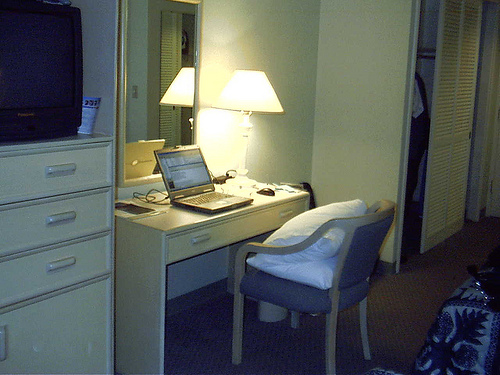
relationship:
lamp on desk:
[209, 64, 287, 183] [111, 171, 314, 374]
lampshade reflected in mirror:
[212, 64, 283, 118] [127, 0, 195, 179]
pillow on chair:
[256, 198, 366, 264] [228, 197, 396, 374]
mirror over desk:
[127, 0, 195, 179] [111, 171, 314, 374]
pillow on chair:
[252, 253, 342, 291] [228, 197, 396, 374]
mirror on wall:
[127, 0, 195, 179] [126, 2, 322, 186]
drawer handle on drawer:
[40, 161, 78, 176] [3, 142, 109, 204]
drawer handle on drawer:
[48, 211, 78, 225] [4, 185, 110, 257]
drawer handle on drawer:
[48, 255, 80, 271] [0, 227, 111, 307]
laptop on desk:
[152, 143, 256, 222] [111, 171, 314, 374]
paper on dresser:
[80, 94, 106, 138] [3, 132, 113, 374]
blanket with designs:
[407, 258, 497, 374] [441, 308, 489, 372]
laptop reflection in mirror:
[119, 135, 164, 180] [127, 0, 195, 179]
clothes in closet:
[401, 65, 429, 185] [393, 1, 489, 274]